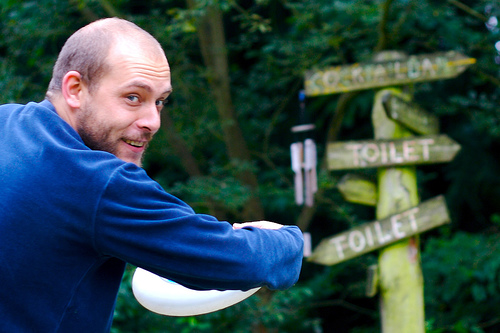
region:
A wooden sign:
[295, 35, 476, 327]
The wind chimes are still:
[283, 113, 325, 214]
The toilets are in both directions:
[307, 121, 474, 318]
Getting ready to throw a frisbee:
[120, 165, 317, 330]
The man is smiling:
[13, 5, 191, 189]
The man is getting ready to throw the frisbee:
[2, 13, 308, 332]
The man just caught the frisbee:
[2, 5, 311, 331]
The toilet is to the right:
[321, 120, 468, 181]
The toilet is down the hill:
[305, 190, 469, 277]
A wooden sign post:
[296, 30, 481, 331]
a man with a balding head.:
[43, 15, 195, 180]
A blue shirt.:
[0, 92, 315, 326]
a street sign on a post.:
[296, 196, 460, 296]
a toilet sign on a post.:
[316, 119, 469, 181]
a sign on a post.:
[292, 23, 487, 100]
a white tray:
[127, 202, 322, 330]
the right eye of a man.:
[101, 70, 157, 115]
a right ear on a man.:
[58, 53, 83, 124]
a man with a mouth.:
[112, 123, 152, 169]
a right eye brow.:
[127, 78, 158, 95]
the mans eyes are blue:
[111, 84, 176, 117]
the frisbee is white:
[127, 280, 242, 325]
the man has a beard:
[75, 117, 110, 142]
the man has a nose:
[139, 110, 164, 137]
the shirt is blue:
[9, 149, 84, 317]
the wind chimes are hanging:
[272, 113, 327, 209]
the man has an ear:
[57, 65, 92, 110]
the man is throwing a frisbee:
[12, 16, 301, 321]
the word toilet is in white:
[319, 206, 446, 258]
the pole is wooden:
[379, 252, 426, 317]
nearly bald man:
[2, 13, 308, 331]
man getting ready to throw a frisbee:
[0, 15, 310, 332]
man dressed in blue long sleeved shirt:
[2, 15, 307, 325]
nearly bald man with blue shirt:
[1, 13, 312, 332]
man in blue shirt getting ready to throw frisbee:
[1, 14, 313, 331]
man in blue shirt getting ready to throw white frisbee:
[2, 17, 313, 332]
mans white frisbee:
[128, 213, 275, 319]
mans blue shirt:
[0, 96, 305, 331]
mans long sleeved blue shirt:
[0, 94, 304, 331]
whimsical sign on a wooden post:
[295, 44, 478, 332]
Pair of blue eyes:
[120, 87, 167, 109]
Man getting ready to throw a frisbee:
[0, 16, 307, 331]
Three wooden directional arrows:
[295, 43, 469, 331]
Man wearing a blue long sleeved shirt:
[0, 16, 305, 331]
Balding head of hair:
[44, 13, 172, 170]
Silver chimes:
[287, 86, 323, 206]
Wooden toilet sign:
[302, 195, 450, 268]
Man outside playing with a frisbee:
[0, 3, 496, 331]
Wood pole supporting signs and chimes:
[291, 43, 478, 332]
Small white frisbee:
[130, 216, 267, 316]